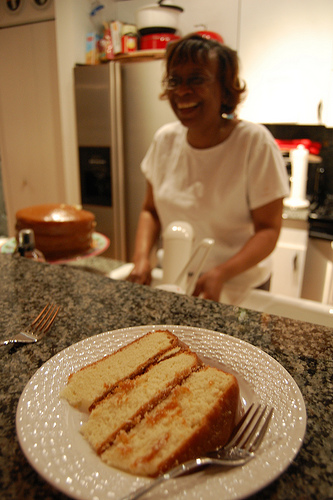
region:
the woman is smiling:
[121, 28, 256, 124]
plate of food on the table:
[6, 323, 307, 484]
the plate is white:
[21, 313, 314, 479]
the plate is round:
[8, 319, 299, 483]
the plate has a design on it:
[9, 308, 310, 468]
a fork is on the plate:
[126, 401, 279, 498]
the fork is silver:
[113, 402, 274, 490]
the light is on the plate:
[19, 399, 105, 483]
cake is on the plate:
[72, 325, 257, 472]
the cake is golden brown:
[58, 309, 252, 474]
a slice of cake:
[62, 325, 240, 482]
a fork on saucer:
[116, 397, 275, 496]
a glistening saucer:
[14, 319, 306, 499]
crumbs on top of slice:
[103, 372, 197, 467]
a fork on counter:
[0, 302, 60, 346]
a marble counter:
[1, 254, 332, 499]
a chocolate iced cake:
[11, 198, 97, 254]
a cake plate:
[1, 230, 110, 263]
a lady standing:
[129, 28, 291, 302]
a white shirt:
[139, 122, 288, 287]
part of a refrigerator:
[68, 58, 165, 262]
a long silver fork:
[104, 398, 279, 498]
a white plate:
[16, 320, 305, 498]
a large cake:
[15, 199, 96, 256]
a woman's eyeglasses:
[160, 70, 213, 91]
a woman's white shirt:
[140, 121, 287, 292]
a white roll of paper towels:
[291, 145, 309, 203]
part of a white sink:
[255, 287, 329, 326]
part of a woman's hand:
[192, 268, 225, 302]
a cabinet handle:
[292, 254, 301, 273]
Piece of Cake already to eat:
[15, 320, 307, 498]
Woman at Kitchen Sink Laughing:
[123, 32, 291, 308]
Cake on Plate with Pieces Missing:
[1, 201, 108, 266]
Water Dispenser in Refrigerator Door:
[73, 143, 116, 210]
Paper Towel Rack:
[283, 143, 309, 211]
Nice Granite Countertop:
[1, 247, 328, 498]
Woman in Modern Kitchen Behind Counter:
[1, 2, 327, 494]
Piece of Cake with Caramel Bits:
[13, 322, 311, 498]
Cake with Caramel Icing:
[9, 199, 100, 266]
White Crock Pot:
[131, 1, 187, 37]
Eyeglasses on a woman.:
[161, 74, 220, 86]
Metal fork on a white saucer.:
[120, 402, 274, 499]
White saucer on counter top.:
[14, 325, 305, 499]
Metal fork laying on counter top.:
[0, 302, 61, 347]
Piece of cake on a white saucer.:
[57, 329, 244, 477]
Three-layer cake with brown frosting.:
[14, 204, 94, 259]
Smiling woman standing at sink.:
[125, 33, 290, 301]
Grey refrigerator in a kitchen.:
[73, 58, 179, 268]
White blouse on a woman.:
[139, 121, 289, 306]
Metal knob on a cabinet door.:
[293, 253, 297, 269]